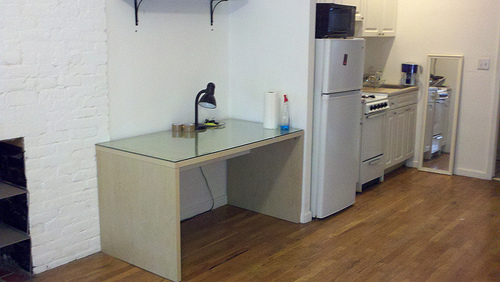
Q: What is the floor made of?
A: Wood.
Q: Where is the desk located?
A: In the corner.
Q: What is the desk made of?
A: Wood and glass.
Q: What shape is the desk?
A: Rectangular.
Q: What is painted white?
A: The brick wall.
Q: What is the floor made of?
A: Brown wood.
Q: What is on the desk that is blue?
A: Cleaner.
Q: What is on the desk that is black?
A: A small lamp.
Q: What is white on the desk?
A: Paper towels.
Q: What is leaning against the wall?
A: A long mirror.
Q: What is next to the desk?
A: A fridge.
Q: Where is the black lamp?
A: On the desk.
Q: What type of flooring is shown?
A: Hardwood.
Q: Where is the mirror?
A: Against the back wall.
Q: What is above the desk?
A: Shelf.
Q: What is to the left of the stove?
A: Refrigerator.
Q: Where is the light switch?
A: Beside the mirror.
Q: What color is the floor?
A: Brown.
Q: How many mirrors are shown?
A: One.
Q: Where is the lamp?
A: On desk.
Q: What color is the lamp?
A: Black.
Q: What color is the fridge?
A: White.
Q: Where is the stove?
A: Beside fridge.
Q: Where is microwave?
A: On fridge.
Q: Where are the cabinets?
A: Above stove.